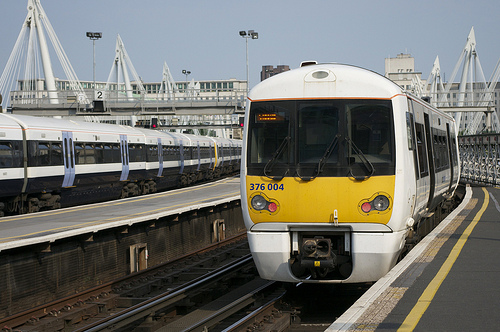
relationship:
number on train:
[247, 181, 287, 193] [231, 66, 468, 283]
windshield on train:
[245, 99, 398, 179] [231, 66, 468, 283]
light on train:
[372, 195, 390, 213] [231, 66, 468, 283]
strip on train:
[242, 174, 398, 227] [231, 66, 468, 283]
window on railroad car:
[301, 106, 345, 178] [231, 66, 468, 283]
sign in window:
[254, 109, 292, 125] [301, 106, 345, 178]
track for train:
[119, 249, 265, 329] [231, 66, 468, 283]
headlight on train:
[249, 194, 283, 220] [231, 66, 468, 283]